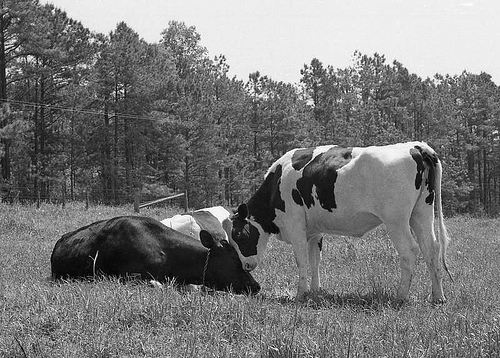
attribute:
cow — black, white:
[231, 141, 456, 308]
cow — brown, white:
[234, 145, 495, 245]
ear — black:
[233, 200, 248, 222]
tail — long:
[416, 140, 458, 285]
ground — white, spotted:
[365, 110, 388, 127]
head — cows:
[223, 200, 270, 274]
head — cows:
[196, 228, 260, 295]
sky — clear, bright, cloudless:
[226, 4, 498, 45]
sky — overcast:
[236, 17, 335, 67]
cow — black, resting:
[48, 214, 260, 296]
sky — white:
[86, 6, 481, 70]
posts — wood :
[32, 186, 199, 213]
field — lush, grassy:
[0, 199, 497, 356]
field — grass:
[10, 231, 481, 355]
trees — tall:
[8, 16, 482, 195]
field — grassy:
[9, 195, 482, 346]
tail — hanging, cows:
[423, 140, 464, 287]